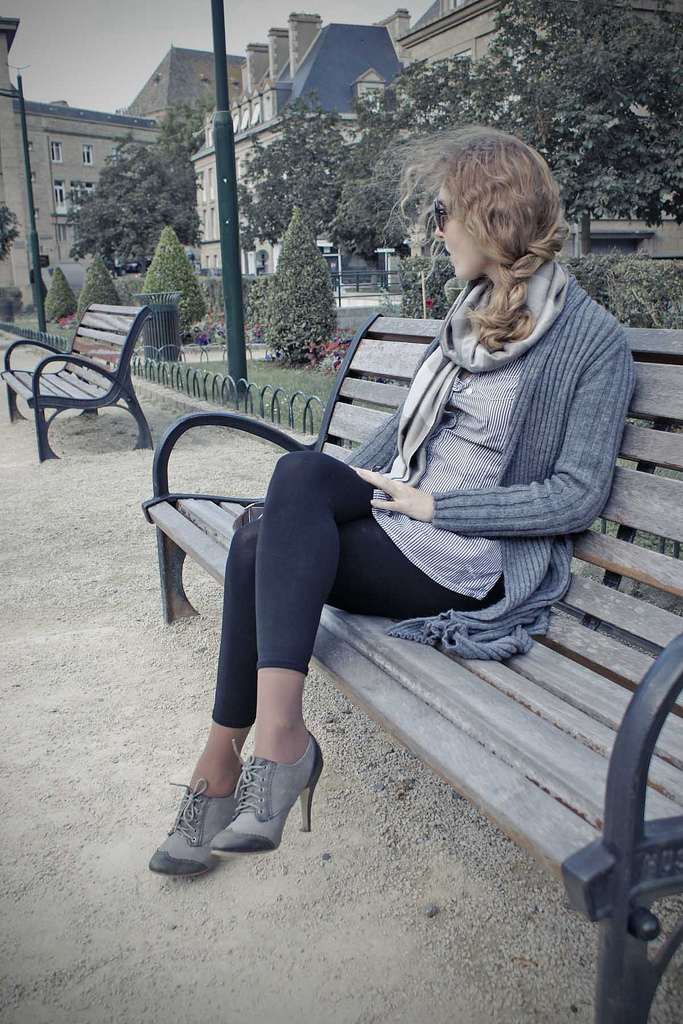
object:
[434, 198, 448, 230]
glasses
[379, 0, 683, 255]
building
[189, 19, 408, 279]
building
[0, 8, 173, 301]
building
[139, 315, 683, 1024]
bench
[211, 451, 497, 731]
black leggings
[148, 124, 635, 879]
woman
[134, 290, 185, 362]
black trashcan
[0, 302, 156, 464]
bench